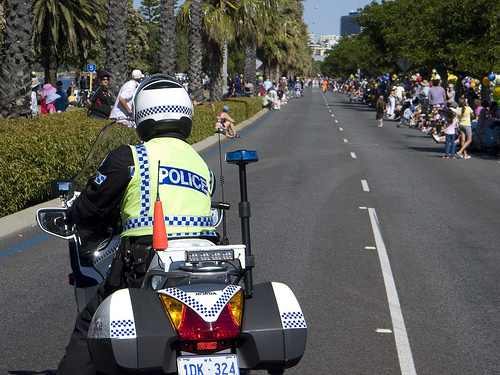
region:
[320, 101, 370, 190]
white lines in the road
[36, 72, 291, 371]
policeman on a motorcycle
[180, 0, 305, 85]
a group of palm trees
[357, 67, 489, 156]
spectators along the street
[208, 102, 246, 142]
two people sitting on a curb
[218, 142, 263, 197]
a blue police light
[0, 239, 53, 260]
blue line parellel to the curb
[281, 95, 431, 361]
an empty street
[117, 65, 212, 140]
a white helmet with black squares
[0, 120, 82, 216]
Green bushes lining the curb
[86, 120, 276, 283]
Jacket on a police man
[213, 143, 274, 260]
Blue light on a motorcycle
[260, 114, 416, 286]
Gray pavement with white stripes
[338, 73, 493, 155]
Crowd next to a road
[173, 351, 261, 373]
White and blue license on a bike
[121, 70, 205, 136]
Helmet on a police man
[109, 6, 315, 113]
Trees by a road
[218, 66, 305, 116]
People sitting by a road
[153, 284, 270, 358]
Red light on a police bike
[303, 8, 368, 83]
Buildings by trees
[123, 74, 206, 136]
Man wears a white and blue helmet.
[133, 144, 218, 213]
Back of man's shirt says police.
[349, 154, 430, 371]
White dotted lines on pavement.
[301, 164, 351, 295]
Grey highway pavement.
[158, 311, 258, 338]
Red light in back of bike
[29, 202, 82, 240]
White trimmed rearview mirror.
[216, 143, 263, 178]
Blue police light on top of pole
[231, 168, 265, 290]
Black pole holding blue police light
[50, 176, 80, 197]
Video camera in front of bike.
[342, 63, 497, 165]
Crowds of people along side the road.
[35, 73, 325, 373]
Policeman on a motorcycle.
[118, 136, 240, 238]
Policeman wearing yellow safety vest trimmed in blue and white checks.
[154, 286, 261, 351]
Break and signal lights on rear of motorcycle.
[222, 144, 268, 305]
Blue emergency light mounted on motorcycle.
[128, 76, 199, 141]
Policeman wearing white helmet.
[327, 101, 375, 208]
White divider lines in middle of street.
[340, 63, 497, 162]
People lined on side of street.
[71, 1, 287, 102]
Palm trees growing on side of street.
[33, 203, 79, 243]
Rear view mirror on motorcycle.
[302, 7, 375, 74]
Tall buildings at end of street in distance.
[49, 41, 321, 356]
a police office on motorcycle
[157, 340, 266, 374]
the plate number is 10k 324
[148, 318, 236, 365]
the license plate is white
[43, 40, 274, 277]
safety vest is green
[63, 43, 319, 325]
the vest has checkered stripes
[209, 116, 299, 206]
police light is blue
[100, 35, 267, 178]
the helmet is white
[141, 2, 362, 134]
the road lined with palm trees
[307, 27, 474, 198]
people at a parade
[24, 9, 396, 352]
police patrolling a parade